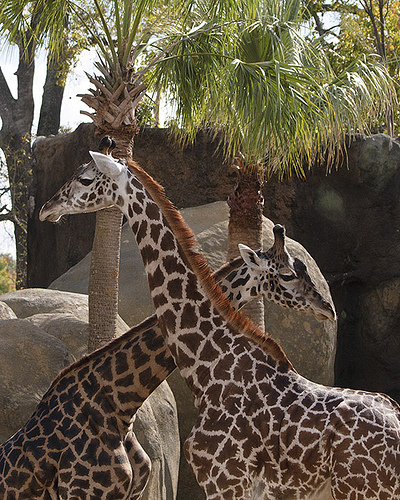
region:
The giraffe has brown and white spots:
[210, 384, 375, 488]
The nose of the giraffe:
[320, 298, 336, 316]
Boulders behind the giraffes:
[8, 205, 321, 496]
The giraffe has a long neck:
[120, 205, 283, 376]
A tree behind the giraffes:
[162, 36, 379, 338]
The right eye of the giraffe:
[276, 271, 298, 283]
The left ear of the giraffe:
[91, 151, 121, 176]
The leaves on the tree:
[154, 4, 391, 167]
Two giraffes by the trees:
[12, 160, 397, 490]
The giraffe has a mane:
[125, 164, 292, 363]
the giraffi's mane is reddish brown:
[124, 157, 310, 377]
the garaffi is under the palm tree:
[67, 1, 133, 337]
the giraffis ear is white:
[85, 148, 125, 182]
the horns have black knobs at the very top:
[94, 134, 118, 159]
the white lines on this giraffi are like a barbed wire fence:
[227, 352, 251, 393]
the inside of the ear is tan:
[238, 242, 266, 275]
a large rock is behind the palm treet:
[0, 286, 182, 498]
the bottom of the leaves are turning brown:
[330, 134, 350, 168]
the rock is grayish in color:
[3, 288, 181, 498]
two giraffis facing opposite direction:
[26, 138, 395, 494]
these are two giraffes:
[17, 154, 310, 496]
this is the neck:
[28, 153, 217, 309]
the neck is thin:
[128, 212, 221, 296]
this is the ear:
[82, 152, 118, 177]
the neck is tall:
[129, 177, 228, 314]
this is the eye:
[78, 172, 95, 185]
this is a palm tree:
[193, 61, 308, 208]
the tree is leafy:
[224, 72, 332, 138]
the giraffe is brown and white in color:
[232, 408, 339, 465]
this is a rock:
[299, 325, 328, 359]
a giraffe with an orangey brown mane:
[38, 134, 397, 496]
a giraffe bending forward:
[0, 224, 334, 496]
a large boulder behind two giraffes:
[45, 201, 336, 499]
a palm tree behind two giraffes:
[157, 1, 371, 334]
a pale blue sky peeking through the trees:
[1, 1, 398, 137]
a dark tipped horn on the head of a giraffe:
[100, 134, 111, 154]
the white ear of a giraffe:
[89, 150, 124, 178]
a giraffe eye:
[79, 176, 93, 187]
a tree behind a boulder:
[0, 34, 89, 290]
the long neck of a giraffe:
[130, 172, 252, 386]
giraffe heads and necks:
[35, 136, 336, 411]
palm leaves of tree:
[22, 3, 391, 153]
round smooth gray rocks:
[2, 197, 334, 492]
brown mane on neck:
[130, 161, 290, 369]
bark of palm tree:
[82, 208, 123, 347]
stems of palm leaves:
[75, 1, 225, 70]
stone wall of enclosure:
[29, 121, 396, 391]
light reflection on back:
[290, 375, 398, 433]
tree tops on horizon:
[0, 249, 15, 296]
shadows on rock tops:
[5, 295, 87, 377]